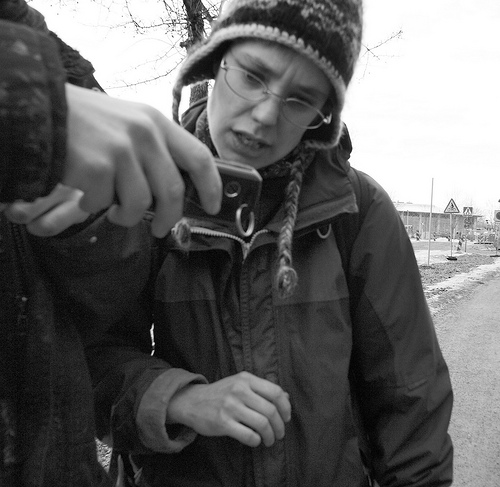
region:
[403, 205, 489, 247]
building in background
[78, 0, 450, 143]
cloudy sky above people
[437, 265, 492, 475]
road behind people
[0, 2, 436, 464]
woman looking down at someone else cell phone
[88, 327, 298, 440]
woman's arm is sticking straight out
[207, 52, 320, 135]
woman wearing glasses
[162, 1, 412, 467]
woman wearing a warm hat looking at cell phone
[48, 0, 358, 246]
man is showing woman cell phone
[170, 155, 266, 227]
black cell phone with eye of the camera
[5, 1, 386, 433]
hand is showing woman how to use the cell phone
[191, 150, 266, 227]
person looking at phone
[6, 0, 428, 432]
person showing girl how to operate cell phone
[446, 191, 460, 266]
traffic triangle sign in background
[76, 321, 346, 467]
girl's hand is stretched out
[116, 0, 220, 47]
tree with no leaves in background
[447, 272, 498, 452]
pavement road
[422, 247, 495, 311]
parking strip with grass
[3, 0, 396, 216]
woman wearing a hat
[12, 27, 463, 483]
woman wearing a coat is looking down at cell phone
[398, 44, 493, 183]
Sky is white color.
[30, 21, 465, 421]
Black and white picture.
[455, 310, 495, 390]
Road is grey color.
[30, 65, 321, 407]
Two person are standing.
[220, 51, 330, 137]
Woman is wearing eyeglass.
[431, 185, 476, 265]
Signs are in sides of the road.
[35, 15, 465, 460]
Day time picture.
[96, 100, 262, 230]
Person is holding the mobile.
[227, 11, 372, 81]
Woman is wearing cap.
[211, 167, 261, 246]
Cellphone has ring in it.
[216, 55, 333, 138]
Boy wearing glasses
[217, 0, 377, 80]
Boy wearing a hat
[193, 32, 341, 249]
Boy looking at a cellphone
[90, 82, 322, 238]
Person holding cellphone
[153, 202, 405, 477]
Boy wearing winter jacket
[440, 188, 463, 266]
Triangle traffic sign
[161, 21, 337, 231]
Boy watching a cellphone screen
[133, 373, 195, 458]
Rolled up jacket sleeve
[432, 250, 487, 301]
Dirt on the ground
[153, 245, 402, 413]
Two tone winter jacket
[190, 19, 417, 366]
a child wearing a winter hat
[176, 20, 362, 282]
a child wearing glasses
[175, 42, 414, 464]
a child wearing a winter coat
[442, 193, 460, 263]
a sign on the street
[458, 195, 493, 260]
a sign on the street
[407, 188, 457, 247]
a building in the distance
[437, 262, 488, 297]
snow on the ground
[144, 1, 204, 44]
bare tree branches above the child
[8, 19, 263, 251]
a person holding an object in their hand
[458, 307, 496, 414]
pavement in the background